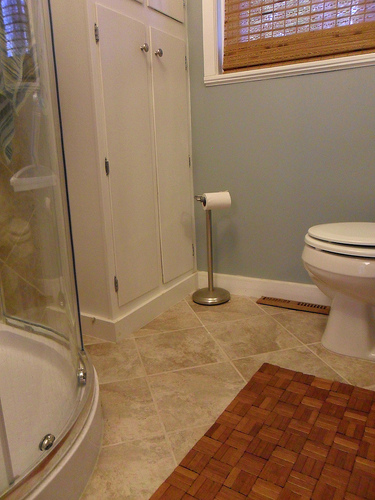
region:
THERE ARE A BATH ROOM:
[1, 161, 374, 499]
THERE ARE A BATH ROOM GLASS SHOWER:
[0, 100, 101, 499]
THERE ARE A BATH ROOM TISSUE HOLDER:
[194, 190, 237, 310]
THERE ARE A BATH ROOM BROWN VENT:
[252, 291, 327, 314]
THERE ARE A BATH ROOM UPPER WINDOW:
[202, 0, 373, 90]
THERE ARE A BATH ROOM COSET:
[26, 0, 198, 338]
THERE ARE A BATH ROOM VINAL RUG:
[84, 287, 374, 496]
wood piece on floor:
[259, 396, 280, 409]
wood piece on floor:
[248, 405, 267, 421]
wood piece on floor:
[253, 424, 276, 439]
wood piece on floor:
[268, 463, 286, 483]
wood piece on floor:
[298, 451, 322, 482]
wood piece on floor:
[312, 432, 331, 447]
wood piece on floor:
[322, 398, 342, 420]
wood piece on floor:
[327, 391, 348, 407]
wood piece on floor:
[300, 387, 319, 408]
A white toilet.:
[300, 220, 374, 361]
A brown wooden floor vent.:
[254, 294, 331, 315]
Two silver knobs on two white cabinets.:
[142, 43, 162, 56]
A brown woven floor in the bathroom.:
[154, 360, 374, 499]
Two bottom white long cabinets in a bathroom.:
[95, 2, 196, 307]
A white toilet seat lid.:
[307, 221, 373, 246]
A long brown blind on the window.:
[217, 2, 372, 75]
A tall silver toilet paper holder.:
[192, 192, 228, 308]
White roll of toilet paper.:
[202, 192, 232, 209]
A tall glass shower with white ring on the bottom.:
[0, 1, 101, 499]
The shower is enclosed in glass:
[27, 195, 112, 479]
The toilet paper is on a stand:
[195, 187, 236, 313]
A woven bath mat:
[198, 396, 346, 483]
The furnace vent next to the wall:
[255, 288, 331, 325]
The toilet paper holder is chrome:
[192, 188, 235, 311]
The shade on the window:
[225, 8, 348, 54]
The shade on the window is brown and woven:
[223, 3, 357, 77]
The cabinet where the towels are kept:
[91, 15, 191, 235]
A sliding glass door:
[0, 2, 91, 484]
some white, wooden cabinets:
[47, 3, 201, 342]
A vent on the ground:
[256, 293, 331, 315]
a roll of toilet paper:
[201, 190, 233, 211]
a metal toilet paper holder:
[190, 194, 230, 304]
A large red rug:
[150, 361, 373, 498]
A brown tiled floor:
[80, 288, 374, 498]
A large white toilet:
[300, 219, 372, 358]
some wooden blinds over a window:
[220, 0, 372, 74]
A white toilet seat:
[307, 221, 373, 247]